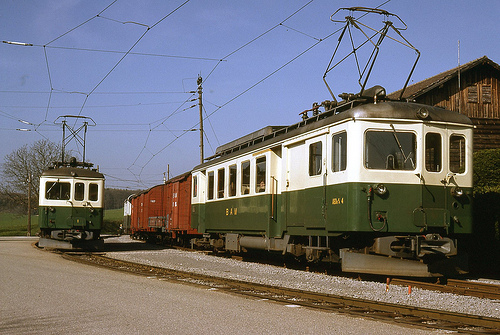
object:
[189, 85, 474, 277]
cars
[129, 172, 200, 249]
car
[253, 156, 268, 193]
windows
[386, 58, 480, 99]
roof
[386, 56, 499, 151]
building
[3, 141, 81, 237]
tree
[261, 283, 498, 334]
tracks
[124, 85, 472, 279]
train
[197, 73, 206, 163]
poles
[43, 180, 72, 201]
window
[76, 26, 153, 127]
lines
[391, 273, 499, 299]
track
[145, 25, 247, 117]
sky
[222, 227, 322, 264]
metal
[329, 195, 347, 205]
number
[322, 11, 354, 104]
conductor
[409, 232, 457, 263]
connecter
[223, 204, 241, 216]
name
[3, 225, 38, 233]
brush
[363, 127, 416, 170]
windshield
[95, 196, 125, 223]
hills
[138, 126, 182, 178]
clouds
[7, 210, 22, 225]
grass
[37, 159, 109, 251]
trains